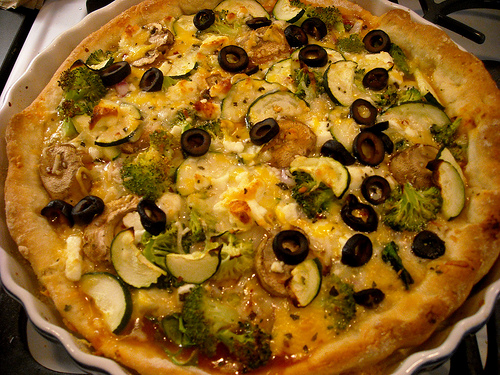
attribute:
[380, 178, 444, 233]
broccoli — flat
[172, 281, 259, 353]
broccoli — flat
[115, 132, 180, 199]
broccoli — flat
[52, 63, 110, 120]
broccoli — flat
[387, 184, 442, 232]
vegetable — green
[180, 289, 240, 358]
vegetable — green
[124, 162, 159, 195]
vegetable — green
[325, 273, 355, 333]
vegetable — green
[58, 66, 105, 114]
vegetable — green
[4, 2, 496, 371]
pizza — Round 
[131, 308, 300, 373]
sauce — red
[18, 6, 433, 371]
pizza — cooked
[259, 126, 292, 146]
olive — sliced